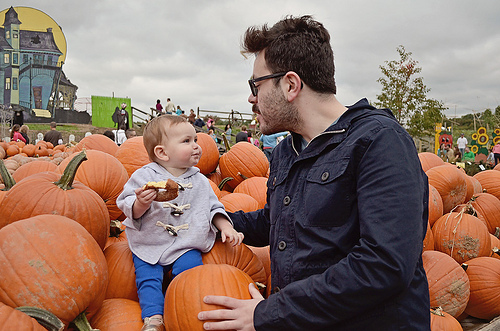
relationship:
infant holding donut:
[115, 108, 247, 330] [138, 176, 181, 204]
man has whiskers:
[192, 8, 440, 330] [257, 79, 306, 137]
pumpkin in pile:
[0, 300, 69, 330] [0, 129, 499, 330]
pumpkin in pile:
[82, 295, 147, 330] [0, 129, 499, 330]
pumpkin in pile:
[1, 210, 112, 330] [0, 129, 499, 330]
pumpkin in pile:
[99, 236, 144, 306] [0, 129, 499, 330]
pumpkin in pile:
[197, 227, 268, 293] [0, 129, 499, 330]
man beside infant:
[192, 8, 440, 330] [115, 108, 247, 330]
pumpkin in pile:
[429, 304, 467, 331] [0, 129, 499, 330]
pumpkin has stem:
[1, 210, 112, 330] [70, 308, 98, 330]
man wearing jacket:
[192, 8, 440, 330] [213, 99, 433, 330]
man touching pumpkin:
[192, 8, 440, 330] [161, 260, 262, 330]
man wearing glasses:
[192, 8, 440, 330] [246, 68, 308, 98]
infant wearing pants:
[115, 108, 247, 330] [130, 246, 207, 323]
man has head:
[192, 8, 440, 330] [238, 9, 357, 146]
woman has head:
[18, 121, 32, 147] [19, 119, 31, 137]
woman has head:
[8, 119, 28, 146] [10, 122, 22, 136]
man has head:
[41, 118, 66, 147] [48, 119, 62, 133]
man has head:
[164, 95, 177, 118] [165, 95, 173, 105]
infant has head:
[115, 108, 247, 330] [142, 111, 205, 176]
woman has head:
[173, 104, 184, 118] [175, 105, 182, 111]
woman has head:
[155, 98, 165, 118] [155, 97, 163, 107]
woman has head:
[185, 105, 197, 124] [189, 106, 195, 115]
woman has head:
[220, 119, 235, 147] [224, 121, 232, 133]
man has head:
[455, 128, 470, 155] [458, 130, 466, 141]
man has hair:
[192, 8, 440, 330] [241, 9, 342, 94]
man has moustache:
[192, 8, 440, 330] [250, 103, 264, 115]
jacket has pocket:
[213, 99, 433, 330] [294, 152, 360, 231]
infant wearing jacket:
[115, 108, 247, 330] [115, 161, 233, 267]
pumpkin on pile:
[418, 243, 474, 320] [0, 129, 499, 330]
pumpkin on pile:
[459, 254, 499, 321] [0, 129, 499, 330]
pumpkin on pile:
[429, 208, 496, 264] [0, 129, 499, 330]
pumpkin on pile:
[456, 191, 500, 239] [0, 129, 499, 330]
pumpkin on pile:
[425, 178, 446, 228] [0, 129, 499, 330]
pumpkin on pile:
[418, 210, 437, 256] [0, 129, 499, 330]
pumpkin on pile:
[422, 161, 471, 217] [0, 129, 499, 330]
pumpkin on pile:
[408, 147, 450, 177] [0, 129, 499, 330]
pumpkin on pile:
[0, 149, 113, 254] [0, 129, 499, 330]